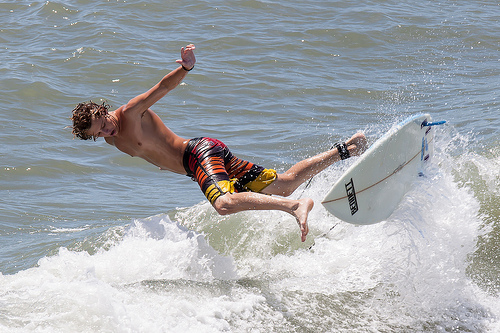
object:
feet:
[294, 198, 316, 241]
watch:
[182, 65, 194, 71]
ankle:
[330, 142, 351, 160]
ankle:
[288, 199, 300, 215]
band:
[181, 65, 194, 71]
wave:
[154, 265, 500, 298]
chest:
[112, 116, 166, 161]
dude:
[70, 43, 367, 241]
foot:
[345, 134, 369, 157]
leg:
[189, 157, 284, 216]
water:
[1, 2, 70, 328]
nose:
[100, 127, 109, 135]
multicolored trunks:
[184, 137, 277, 205]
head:
[62, 99, 123, 141]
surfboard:
[321, 112, 446, 225]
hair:
[73, 103, 106, 119]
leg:
[234, 148, 339, 198]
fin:
[420, 119, 446, 130]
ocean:
[273, 12, 396, 101]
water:
[203, 76, 258, 125]